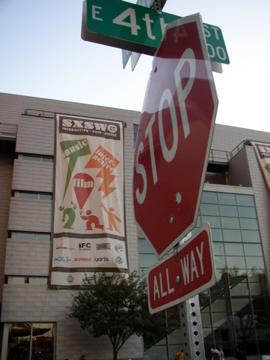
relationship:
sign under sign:
[140, 218, 216, 314] [127, 11, 221, 261]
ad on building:
[46, 108, 138, 288] [5, 90, 256, 356]